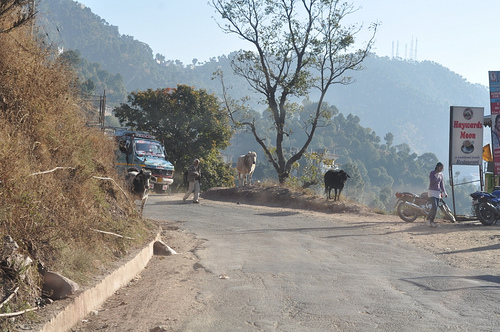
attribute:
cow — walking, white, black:
[322, 169, 349, 203]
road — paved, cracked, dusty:
[138, 195, 497, 331]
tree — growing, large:
[218, 0, 378, 187]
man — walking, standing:
[183, 158, 206, 205]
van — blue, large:
[101, 122, 173, 195]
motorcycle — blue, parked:
[396, 185, 458, 225]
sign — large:
[448, 105, 484, 221]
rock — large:
[332, 205, 351, 213]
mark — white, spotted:
[455, 139, 458, 145]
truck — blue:
[117, 129, 174, 195]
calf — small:
[236, 150, 261, 186]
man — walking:
[424, 163, 445, 226]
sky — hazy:
[86, 0, 499, 81]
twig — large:
[289, 18, 346, 175]